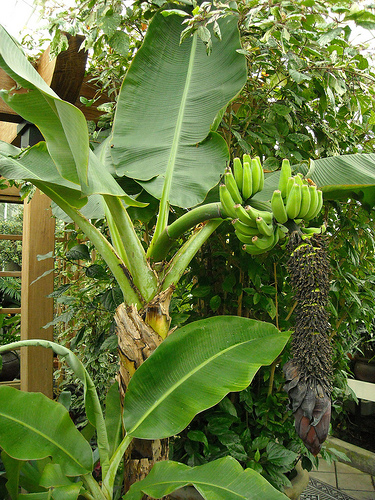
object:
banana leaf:
[119, 311, 297, 444]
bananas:
[219, 183, 238, 219]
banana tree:
[0, 4, 375, 499]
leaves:
[0, 20, 148, 209]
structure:
[0, 175, 53, 401]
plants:
[181, 376, 306, 489]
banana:
[270, 189, 291, 225]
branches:
[66, 177, 230, 313]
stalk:
[107, 201, 162, 303]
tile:
[312, 452, 373, 491]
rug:
[294, 471, 354, 498]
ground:
[275, 370, 375, 498]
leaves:
[111, 2, 254, 222]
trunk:
[113, 287, 179, 499]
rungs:
[0, 192, 23, 389]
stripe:
[123, 332, 259, 433]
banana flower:
[284, 235, 335, 452]